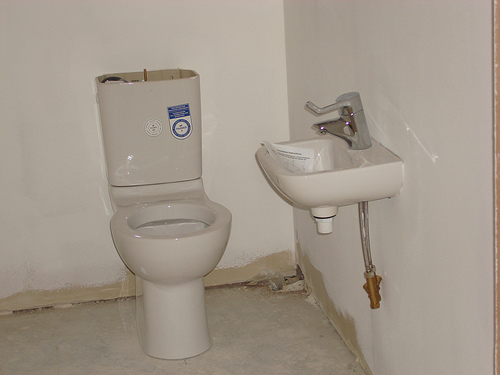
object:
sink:
[254, 137, 404, 234]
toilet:
[95, 67, 232, 360]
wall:
[283, 0, 495, 374]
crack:
[295, 231, 372, 375]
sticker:
[167, 103, 195, 142]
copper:
[362, 271, 382, 310]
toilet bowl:
[109, 190, 231, 285]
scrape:
[300, 258, 313, 289]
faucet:
[305, 91, 372, 150]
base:
[134, 273, 212, 359]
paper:
[260, 141, 315, 174]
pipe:
[357, 201, 376, 274]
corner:
[245, 263, 320, 310]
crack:
[295, 264, 305, 281]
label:
[143, 117, 163, 137]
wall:
[0, 0, 295, 316]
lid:
[109, 193, 231, 240]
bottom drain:
[310, 204, 338, 234]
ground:
[0, 274, 367, 375]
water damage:
[229, 285, 321, 311]